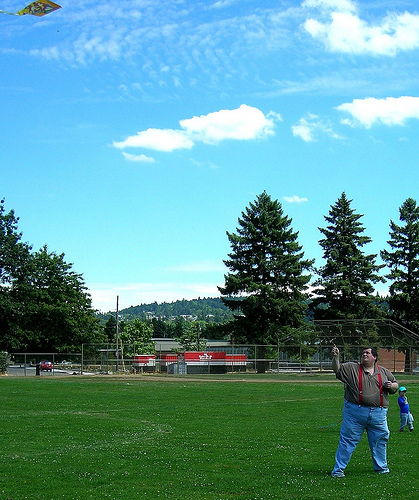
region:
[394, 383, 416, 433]
Boy wearing blue shirt and blue jeans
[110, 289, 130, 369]
Tall telephone pole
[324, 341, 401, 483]
Man wearing brown shirt, red suspenders, and jeans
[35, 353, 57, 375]
Small red car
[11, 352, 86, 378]
Gray parking lot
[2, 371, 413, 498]
Dark green grass field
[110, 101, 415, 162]
White clouds in a blue sky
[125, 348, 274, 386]
Red and white building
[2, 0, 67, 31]
Yellow kite with pattern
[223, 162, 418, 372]
Three tall green trees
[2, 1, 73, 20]
A colorful kite in blue sky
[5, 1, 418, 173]
blue sky with white clouds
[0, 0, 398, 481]
A guy flying a kite in a park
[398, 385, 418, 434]
A boy with green hat in a park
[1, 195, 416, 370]
Trees growing near a park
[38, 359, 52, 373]
A red car driving on the street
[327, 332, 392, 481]
A person wearing blue jeans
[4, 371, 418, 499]
Green grass land in a park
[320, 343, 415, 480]
A boy standing behind a guy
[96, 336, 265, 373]
Red buildings behind the fence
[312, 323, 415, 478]
A man and a boy in a park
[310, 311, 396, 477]
A big man flying a kite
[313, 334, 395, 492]
A man standing in the grass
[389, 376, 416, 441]
A boy standing in the grass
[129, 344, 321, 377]
A fence in front of a building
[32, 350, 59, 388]
A red car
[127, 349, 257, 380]
A red and white building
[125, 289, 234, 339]
A mountain in the background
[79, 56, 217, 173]
Clouds in the sky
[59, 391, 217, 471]
Green grass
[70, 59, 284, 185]
Blue sky filled with clouds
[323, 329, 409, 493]
Man pointing up to the sky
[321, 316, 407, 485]
Man wearing suspenders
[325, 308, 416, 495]
A man and child standing in the grass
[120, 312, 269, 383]
A red building in the distance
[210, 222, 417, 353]
Evergreen trees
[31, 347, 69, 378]
A red car driving down the road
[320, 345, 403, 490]
Man wearing jeans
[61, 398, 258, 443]
Green Grass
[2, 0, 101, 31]
A kite in the sky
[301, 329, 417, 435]
A man and a boy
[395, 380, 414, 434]
A boy wearing a green hat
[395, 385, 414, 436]
A boy wearing a blue shirt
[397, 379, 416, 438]
A boy wearing a blue pants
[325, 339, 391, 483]
A man wearing a blue pants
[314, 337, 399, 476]
A man wearing a brown shirt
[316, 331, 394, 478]
A man wearing red suspenders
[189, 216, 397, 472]
A man flying a kite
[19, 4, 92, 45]
A kite in the sky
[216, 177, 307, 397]
A big tree